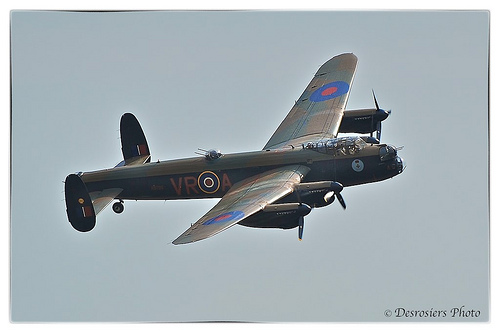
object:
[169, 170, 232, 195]
letters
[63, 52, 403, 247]
plane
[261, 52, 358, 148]
wing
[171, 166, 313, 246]
wing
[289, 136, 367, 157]
cockpit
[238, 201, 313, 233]
engine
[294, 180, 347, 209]
engine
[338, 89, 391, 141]
engine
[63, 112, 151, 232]
tail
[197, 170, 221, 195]
logo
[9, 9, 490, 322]
sky